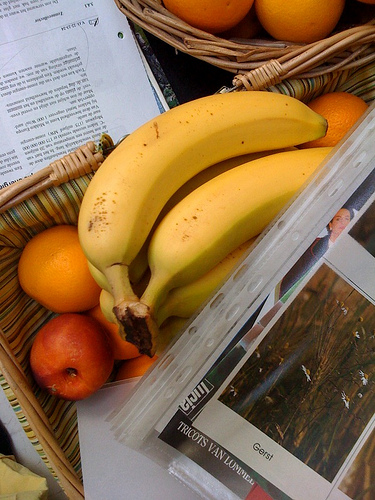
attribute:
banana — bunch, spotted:
[78, 88, 329, 317]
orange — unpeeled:
[18, 224, 103, 314]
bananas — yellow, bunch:
[76, 88, 336, 359]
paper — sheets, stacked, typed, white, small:
[0, 1, 174, 186]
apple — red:
[28, 314, 116, 401]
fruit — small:
[14, 88, 363, 400]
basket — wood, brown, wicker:
[0, 26, 374, 499]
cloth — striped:
[0, 68, 375, 491]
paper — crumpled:
[157, 167, 373, 499]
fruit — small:
[162, 1, 342, 41]